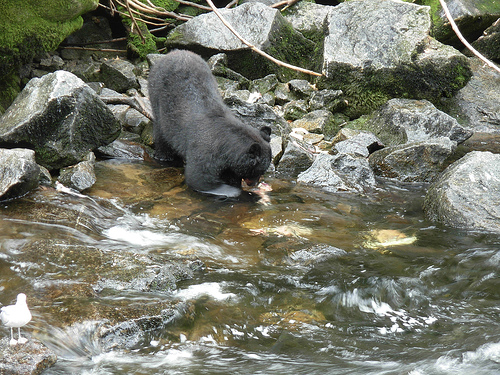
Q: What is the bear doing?
A: Catching a fish.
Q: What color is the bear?
A: Grey.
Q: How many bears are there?
A: One.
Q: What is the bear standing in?
A: A stream.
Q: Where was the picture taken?
A: In the woods.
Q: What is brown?
A: Rocks in the water.